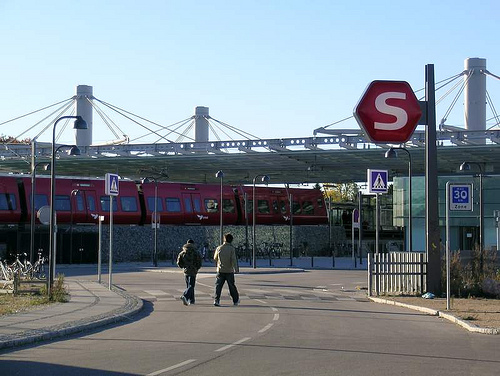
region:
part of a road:
[300, 318, 343, 348]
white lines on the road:
[241, 315, 277, 347]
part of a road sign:
[442, 185, 474, 216]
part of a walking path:
[73, 279, 118, 309]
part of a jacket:
[216, 253, 233, 274]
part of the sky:
[259, 110, 299, 130]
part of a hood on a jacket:
[176, 242, 193, 257]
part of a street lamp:
[458, 160, 468, 178]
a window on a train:
[162, 194, 182, 208]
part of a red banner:
[370, 87, 408, 129]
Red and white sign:
[359, 72, 422, 147]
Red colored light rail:
[8, 167, 335, 233]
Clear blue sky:
[18, 15, 241, 77]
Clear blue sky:
[238, 11, 453, 53]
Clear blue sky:
[188, 14, 303, 102]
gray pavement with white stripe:
[146, 310, 358, 363]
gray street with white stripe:
[151, 315, 398, 364]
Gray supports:
[43, 85, 281, 152]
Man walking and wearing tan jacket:
[203, 225, 256, 312]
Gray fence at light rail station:
[364, 240, 437, 313]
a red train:
[1, 172, 339, 230]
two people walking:
[153, 223, 280, 318]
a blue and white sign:
[359, 165, 396, 207]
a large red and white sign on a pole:
[282, 60, 455, 297]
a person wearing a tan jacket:
[207, 231, 248, 308]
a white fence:
[347, 243, 436, 289]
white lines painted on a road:
[175, 287, 287, 374]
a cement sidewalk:
[4, 270, 144, 352]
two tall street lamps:
[31, 112, 94, 307]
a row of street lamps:
[88, 170, 346, 281]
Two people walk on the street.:
[162, 221, 278, 315]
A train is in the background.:
[0, 176, 347, 252]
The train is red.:
[0, 160, 350, 239]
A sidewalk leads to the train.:
[0, 257, 145, 368]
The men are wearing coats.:
[168, 237, 245, 279]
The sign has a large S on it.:
[347, 75, 430, 146]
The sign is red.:
[341, 72, 421, 152]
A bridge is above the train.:
[0, 52, 497, 185]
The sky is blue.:
[0, 0, 499, 81]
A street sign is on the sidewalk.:
[103, 165, 140, 295]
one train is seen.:
[11, 173, 341, 244]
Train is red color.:
[12, 172, 352, 237]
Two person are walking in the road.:
[165, 230, 253, 315]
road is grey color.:
[276, 295, 352, 363]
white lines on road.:
[171, 296, 307, 361]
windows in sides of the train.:
[10, 190, 331, 222]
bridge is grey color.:
[67, 97, 403, 169]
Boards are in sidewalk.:
[365, 166, 481, 302]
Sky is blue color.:
[117, 30, 313, 91]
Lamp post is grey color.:
[46, 116, 83, 292]